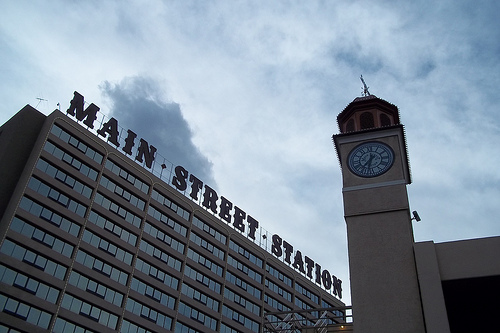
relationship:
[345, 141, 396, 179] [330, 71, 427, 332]
clock on tower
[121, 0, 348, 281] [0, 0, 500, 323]
cloud in sky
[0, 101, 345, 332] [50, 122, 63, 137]
building has window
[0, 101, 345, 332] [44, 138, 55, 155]
building has window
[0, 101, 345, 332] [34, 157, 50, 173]
building has window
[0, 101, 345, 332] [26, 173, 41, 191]
building has window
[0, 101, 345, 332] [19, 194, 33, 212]
building has window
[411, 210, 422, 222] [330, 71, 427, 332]
security camera on tower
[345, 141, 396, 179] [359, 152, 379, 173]
clock reads 6:35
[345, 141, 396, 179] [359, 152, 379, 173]
clock shows 7:30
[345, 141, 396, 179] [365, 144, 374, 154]
clock has roman numerals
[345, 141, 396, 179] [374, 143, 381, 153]
clock has roman numerals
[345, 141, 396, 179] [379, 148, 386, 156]
clock has roman numerals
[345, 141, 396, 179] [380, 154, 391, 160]
clock has roman numerals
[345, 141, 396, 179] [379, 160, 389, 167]
clock has roman numerals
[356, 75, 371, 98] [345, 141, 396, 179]
statue above clock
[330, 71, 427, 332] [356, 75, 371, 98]
tower has statue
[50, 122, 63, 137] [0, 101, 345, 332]
window on building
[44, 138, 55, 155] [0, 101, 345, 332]
window on building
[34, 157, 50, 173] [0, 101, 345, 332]
window on building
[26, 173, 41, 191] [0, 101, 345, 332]
window on building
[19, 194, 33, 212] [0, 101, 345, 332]
window on building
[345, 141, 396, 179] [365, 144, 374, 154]
clock with roman numerals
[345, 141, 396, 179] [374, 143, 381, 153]
clock with roman numerals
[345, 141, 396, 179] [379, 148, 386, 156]
clock with roman numerals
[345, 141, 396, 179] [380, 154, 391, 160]
clock with roman numerals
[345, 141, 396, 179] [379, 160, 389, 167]
clock with roman numerals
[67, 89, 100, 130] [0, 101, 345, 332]
letter above building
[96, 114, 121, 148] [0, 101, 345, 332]
letter above building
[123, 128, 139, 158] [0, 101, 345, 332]
letter above building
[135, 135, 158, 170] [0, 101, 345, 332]
letter above building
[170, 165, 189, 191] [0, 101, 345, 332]
letter above building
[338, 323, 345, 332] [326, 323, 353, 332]
light on wall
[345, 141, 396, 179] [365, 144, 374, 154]
clock using roman numerals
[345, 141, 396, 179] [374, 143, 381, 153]
clock using roman numerals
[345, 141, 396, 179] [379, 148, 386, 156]
clock using roman numerals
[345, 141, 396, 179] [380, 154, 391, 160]
clock using roman numerals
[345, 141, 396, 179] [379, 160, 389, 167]
clock using roman numerals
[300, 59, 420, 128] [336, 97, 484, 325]
statue on top of building